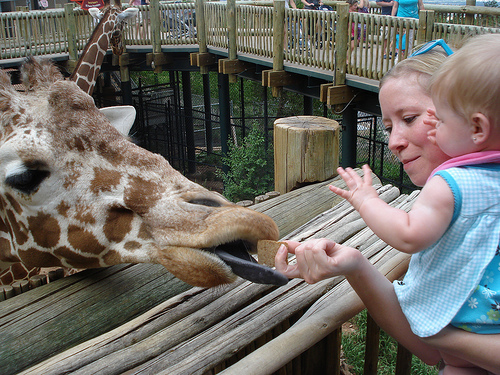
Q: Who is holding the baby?
A: A woman.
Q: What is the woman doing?
A: Feeding the giraffe.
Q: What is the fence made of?
A: Wood.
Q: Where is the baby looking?
A: At the giraffe.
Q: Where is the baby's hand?
A: On its mother's face.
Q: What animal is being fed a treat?
A: Giraffe.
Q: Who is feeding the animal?
A: Woman holding baby.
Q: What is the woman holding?
A: A baby.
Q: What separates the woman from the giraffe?
A: Wooden fence.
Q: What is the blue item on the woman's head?
A: Sunglasses.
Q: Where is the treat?
A: Giraffe's mouth.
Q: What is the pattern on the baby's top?
A: Checkers.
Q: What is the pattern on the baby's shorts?
A: Flowers.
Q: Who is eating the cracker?
A: Giraffe.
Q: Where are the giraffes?
A: Zoo.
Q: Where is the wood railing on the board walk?
A: Behind the woman, child and Giraffe.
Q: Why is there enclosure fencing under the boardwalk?
A: To keep everyone safe.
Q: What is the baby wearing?
A: The baby is wearing a blue dress and a pink bib.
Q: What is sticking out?
A: The Giraffe's tongue.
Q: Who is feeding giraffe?
A: The woman that's holding the baby.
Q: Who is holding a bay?
A: The woman who's feeding the giraffe.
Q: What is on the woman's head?
A: Blue sunglasses.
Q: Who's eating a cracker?
A: The brown Giraffe.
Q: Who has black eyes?
A: The Giraffe has black eyes.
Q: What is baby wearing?
A: Blue dress.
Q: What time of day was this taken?
A: Daytime.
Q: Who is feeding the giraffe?
A: The mother.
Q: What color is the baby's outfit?
A: Blue.